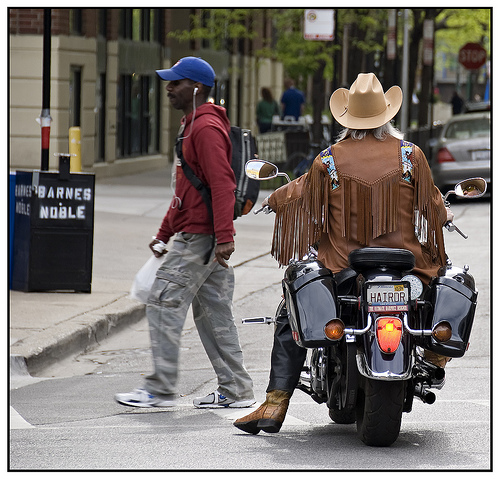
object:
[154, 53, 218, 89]
cap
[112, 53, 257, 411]
man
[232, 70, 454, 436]
man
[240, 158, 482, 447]
motorcycle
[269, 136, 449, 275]
jacket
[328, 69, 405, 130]
hat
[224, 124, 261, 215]
backpack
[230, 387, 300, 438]
boot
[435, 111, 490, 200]
car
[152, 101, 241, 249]
sweater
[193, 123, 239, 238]
sleeves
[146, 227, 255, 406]
pants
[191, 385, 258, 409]
shoes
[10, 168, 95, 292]
dispenser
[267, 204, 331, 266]
tassels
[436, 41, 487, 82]
sign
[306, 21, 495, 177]
intersection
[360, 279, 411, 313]
plate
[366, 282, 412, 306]
hairdr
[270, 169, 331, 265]
fringe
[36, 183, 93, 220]
sign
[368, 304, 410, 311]
illinois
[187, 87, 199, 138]
buds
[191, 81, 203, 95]
ears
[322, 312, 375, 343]
signals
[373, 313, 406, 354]
light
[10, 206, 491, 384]
street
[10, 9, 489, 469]
city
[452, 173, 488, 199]
mirror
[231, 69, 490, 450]
woman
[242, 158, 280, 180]
mirror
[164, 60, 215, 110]
head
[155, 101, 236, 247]
jacket